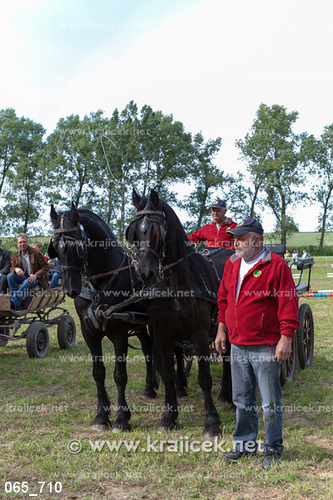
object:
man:
[212, 215, 299, 464]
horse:
[44, 198, 137, 438]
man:
[5, 231, 51, 308]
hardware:
[79, 288, 150, 332]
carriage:
[267, 237, 315, 384]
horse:
[121, 187, 225, 433]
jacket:
[9, 248, 46, 274]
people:
[0, 192, 315, 465]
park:
[0, 28, 333, 279]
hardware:
[0, 274, 69, 355]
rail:
[173, 225, 247, 259]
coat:
[214, 252, 292, 339]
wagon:
[1, 262, 76, 363]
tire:
[56, 316, 77, 349]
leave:
[214, 133, 222, 153]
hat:
[226, 214, 264, 242]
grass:
[9, 439, 118, 469]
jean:
[228, 344, 282, 448]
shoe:
[223, 437, 285, 465]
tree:
[249, 99, 305, 250]